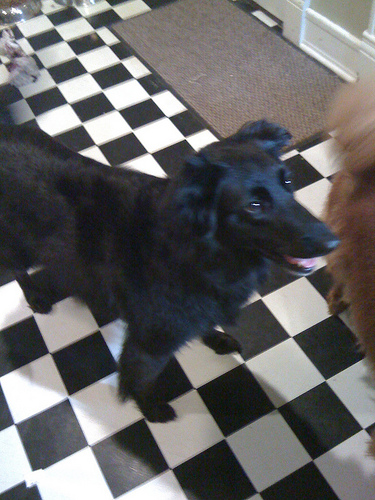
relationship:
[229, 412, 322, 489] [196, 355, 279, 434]
white square by black square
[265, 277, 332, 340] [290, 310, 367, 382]
white square by black square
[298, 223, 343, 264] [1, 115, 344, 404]
nose on dog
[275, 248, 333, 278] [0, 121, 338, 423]
mouth on black dog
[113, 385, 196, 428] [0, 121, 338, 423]
paw on black dog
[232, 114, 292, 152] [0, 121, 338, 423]
ears on black dog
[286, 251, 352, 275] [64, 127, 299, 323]
tongue on dog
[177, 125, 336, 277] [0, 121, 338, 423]
head on black dog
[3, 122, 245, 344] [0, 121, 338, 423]
body on black dog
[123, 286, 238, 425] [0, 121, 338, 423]
legs on black dog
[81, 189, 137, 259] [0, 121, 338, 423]
fur on black dog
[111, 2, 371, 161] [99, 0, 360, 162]
doormat on floor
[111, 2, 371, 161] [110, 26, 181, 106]
doormat has edges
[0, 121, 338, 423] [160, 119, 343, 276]
black dog has head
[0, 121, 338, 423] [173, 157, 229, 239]
black dog has ear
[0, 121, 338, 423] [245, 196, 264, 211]
black dog has dogeye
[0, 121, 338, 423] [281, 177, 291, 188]
black dog has eye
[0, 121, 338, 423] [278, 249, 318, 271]
black dog has tongue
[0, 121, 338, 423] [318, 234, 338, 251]
black dog has nose